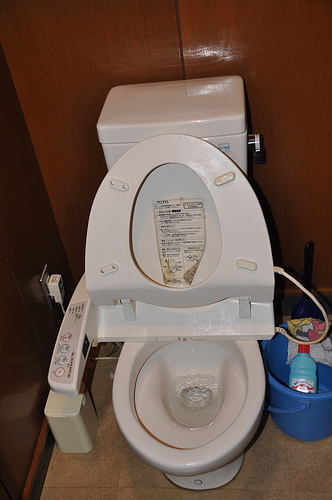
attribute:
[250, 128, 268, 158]
knob — silver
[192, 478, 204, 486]
button — round, white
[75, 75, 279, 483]
toilet — white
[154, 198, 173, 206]
writing — black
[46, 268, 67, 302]
socket — silver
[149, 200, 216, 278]
sign — written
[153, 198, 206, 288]
sign — written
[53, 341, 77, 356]
sign — written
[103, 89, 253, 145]
tank — white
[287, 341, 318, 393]
bottle — blue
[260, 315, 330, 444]
bucket — blue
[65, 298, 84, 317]
writing — black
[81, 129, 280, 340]
lid — raised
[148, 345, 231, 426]
water — clear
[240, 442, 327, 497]
floor — clean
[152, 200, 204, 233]
writing — black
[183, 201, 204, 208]
writing — black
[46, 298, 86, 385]
sign — written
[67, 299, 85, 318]
writing — BLACK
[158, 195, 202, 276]
writing — black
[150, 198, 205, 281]
writing — black